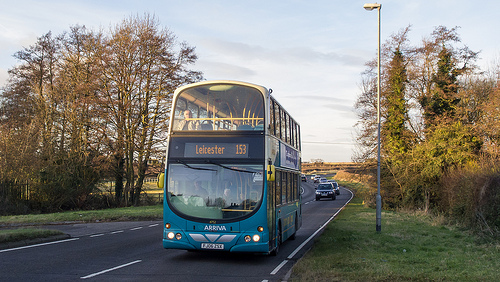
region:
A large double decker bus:
[147, 81, 314, 257]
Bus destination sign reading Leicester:
[170, 132, 257, 165]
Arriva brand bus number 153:
[149, 70, 307, 265]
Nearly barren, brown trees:
[10, 22, 192, 221]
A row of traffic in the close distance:
[300, 161, 350, 210]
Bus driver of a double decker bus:
[172, 168, 223, 220]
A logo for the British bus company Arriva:
[184, 217, 241, 238]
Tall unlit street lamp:
[358, 3, 391, 234]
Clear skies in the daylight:
[5, 0, 497, 159]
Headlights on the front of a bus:
[146, 218, 276, 249]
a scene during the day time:
[13, 13, 495, 261]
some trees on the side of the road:
[343, 28, 497, 228]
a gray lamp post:
[360, 1, 394, 238]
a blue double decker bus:
[147, 48, 315, 280]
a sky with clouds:
[15, 9, 499, 110]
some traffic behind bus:
[285, 143, 382, 240]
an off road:
[0, 211, 150, 239]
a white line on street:
[70, 253, 145, 280]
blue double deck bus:
[168, 83, 290, 253]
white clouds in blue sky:
[284, 13, 354, 44]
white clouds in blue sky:
[295, 61, 309, 83]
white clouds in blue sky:
[214, 25, 268, 70]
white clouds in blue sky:
[307, 51, 344, 92]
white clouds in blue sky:
[301, 72, 335, 122]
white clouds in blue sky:
[452, 21, 492, 52]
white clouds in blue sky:
[175, 19, 249, 63]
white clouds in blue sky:
[267, 16, 322, 47]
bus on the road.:
[160, 67, 310, 261]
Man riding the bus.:
[176, 107, 198, 132]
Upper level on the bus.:
[165, 75, 302, 150]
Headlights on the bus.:
[164, 222, 267, 244]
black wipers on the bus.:
[176, 153, 254, 178]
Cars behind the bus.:
[310, 175, 336, 205]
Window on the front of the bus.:
[162, 154, 267, 230]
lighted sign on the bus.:
[190, 141, 250, 158]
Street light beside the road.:
[360, 0, 390, 232]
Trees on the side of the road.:
[380, 44, 469, 219]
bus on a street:
[155, 72, 311, 264]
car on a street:
[311, 179, 339, 205]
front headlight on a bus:
[242, 230, 265, 246]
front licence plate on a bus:
[195, 237, 229, 255]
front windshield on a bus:
[160, 153, 271, 226]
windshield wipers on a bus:
[173, 156, 263, 178]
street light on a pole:
[356, 0, 384, 30]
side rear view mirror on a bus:
[262, 156, 278, 188]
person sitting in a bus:
[173, 105, 199, 136]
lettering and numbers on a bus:
[183, 137, 255, 159]